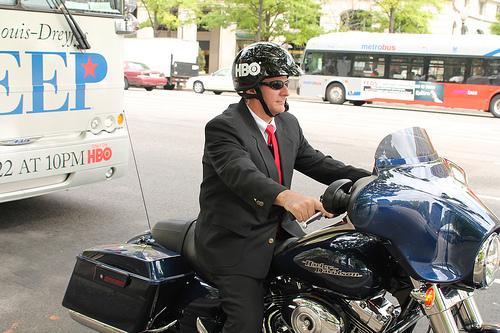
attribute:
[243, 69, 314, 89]
sunglasses — black